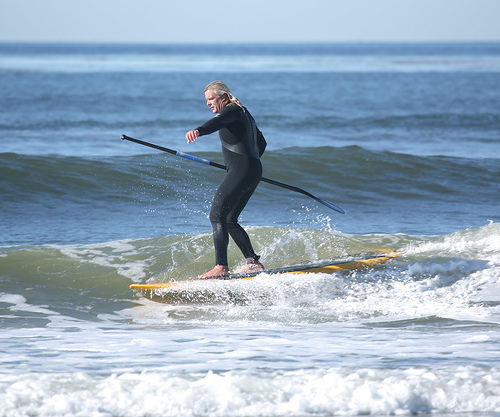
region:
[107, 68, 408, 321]
a man paddle surfing in the waves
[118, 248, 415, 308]
a yellow and black surfboard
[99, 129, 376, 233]
a black and blue paddle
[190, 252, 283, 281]
a man's feet on a surfboard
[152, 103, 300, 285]
a man's black wetsuit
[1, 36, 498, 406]
small coastal ocean waves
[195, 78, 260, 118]
a man's wet blonde hair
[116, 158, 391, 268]
water splashing up around man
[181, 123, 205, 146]
a man's bare hand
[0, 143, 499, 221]
a wave forming on the coast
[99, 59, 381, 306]
a man is surfing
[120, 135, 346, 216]
long, black and blue pole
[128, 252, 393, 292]
yellow and black surfboard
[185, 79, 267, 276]
Man surfing in the ocean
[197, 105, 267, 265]
black wet suit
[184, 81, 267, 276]
man on surfboard in the ocean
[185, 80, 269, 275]
elder man with long black hair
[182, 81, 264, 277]
man holding pole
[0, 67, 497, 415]
large, blue body of water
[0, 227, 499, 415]
white, foamy area of water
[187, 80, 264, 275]
man surfing in the ocean on a yellow surfboard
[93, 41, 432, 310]
A man on a surfboard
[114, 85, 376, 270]
A man holding a black paddle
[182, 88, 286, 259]
A man in a black wetsuit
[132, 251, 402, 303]
A yellow and black surfboard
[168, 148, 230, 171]
Blue area on black paddle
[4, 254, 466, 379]
White foam from waves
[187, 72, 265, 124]
Man has long blond hair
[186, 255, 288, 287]
No shoes on his feet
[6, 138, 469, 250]
A wave coming in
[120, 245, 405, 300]
Surfboard on top of water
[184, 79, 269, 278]
woman in black wetsuit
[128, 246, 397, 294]
woman on yellow surfboard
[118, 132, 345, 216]
woman holding black paddle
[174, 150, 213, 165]
blue strip on handle of paddle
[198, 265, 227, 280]
foot is bare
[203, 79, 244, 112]
hair is long and blonde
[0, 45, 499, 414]
ocean is blue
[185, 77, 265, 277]
person riding wave on surfboard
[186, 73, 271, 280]
person balancing on surfboard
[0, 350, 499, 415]
wave is white and foamy